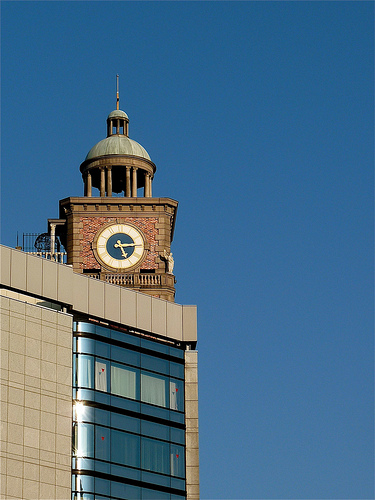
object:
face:
[96, 222, 145, 270]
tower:
[57, 74, 178, 303]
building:
[0, 74, 199, 495]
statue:
[162, 248, 173, 275]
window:
[110, 362, 135, 399]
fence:
[89, 282, 114, 302]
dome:
[106, 109, 129, 121]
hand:
[116, 239, 127, 259]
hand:
[112, 242, 144, 249]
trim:
[70, 314, 109, 370]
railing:
[85, 272, 175, 285]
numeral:
[117, 224, 123, 235]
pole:
[115, 74, 119, 109]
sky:
[3, 5, 374, 500]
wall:
[2, 293, 78, 500]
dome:
[79, 135, 157, 176]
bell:
[90, 219, 150, 272]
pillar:
[99, 170, 104, 197]